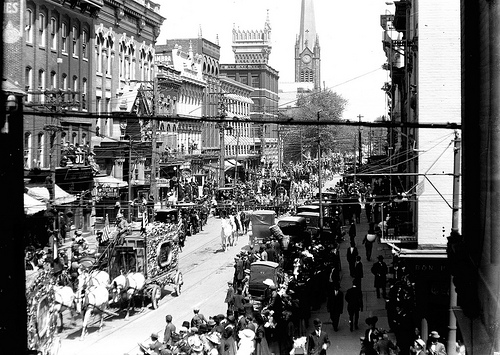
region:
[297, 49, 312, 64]
clock on side of tower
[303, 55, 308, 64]
white face of lcock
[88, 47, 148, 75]
white columns on side of building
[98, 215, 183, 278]
large carriage going down street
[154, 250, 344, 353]
crowds of people gathered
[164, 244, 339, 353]
groups of people watching procession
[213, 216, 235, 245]
white horse walking down street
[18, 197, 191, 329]
horses pulling a cart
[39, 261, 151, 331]
four horses pulling a cart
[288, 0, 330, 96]
a tower on the background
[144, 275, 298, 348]
viewers on side the street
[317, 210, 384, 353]
people walking on side walk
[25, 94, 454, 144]
a pole above the street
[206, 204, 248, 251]
horses walking on the road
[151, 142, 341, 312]
people watching a parade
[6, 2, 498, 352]
The picture is in black and white.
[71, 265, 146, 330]
The horses are white.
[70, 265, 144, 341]
The horses are pulling a carriage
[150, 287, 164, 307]
The front wheel of the carriage is round.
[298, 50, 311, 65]
The clock has a white face.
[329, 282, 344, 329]
The man is wearing a black suit.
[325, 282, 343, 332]
The man is walking on the sidewalk.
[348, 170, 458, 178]
The pipe in the background is thin.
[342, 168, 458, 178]
The pipe is made of metal.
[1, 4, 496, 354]
a white and black photo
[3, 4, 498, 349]
a scene outside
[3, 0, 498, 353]
a scene of downtown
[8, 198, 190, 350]
a carriage being pulled by the horses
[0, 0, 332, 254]
a row of buildings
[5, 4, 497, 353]
a scene during the day time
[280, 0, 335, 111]
a clock tower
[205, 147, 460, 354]
a group of people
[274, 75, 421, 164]
a couple of trees in the distance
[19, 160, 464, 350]
a road in the center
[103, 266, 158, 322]
a horse pulling a carriage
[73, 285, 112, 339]
a horse pulling a carriage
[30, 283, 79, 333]
a horse pulling a carriage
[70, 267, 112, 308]
a horse pulling a carriage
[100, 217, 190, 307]
a carriage pulled by horses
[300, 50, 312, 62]
a clock on a tower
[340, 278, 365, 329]
a person walking on a street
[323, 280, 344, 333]
a person walking on a street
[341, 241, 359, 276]
a person walking on a street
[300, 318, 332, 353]
a person walking on a street